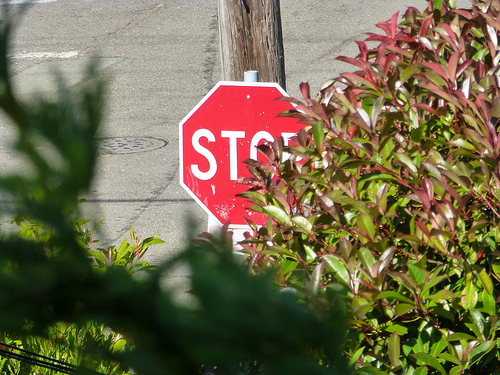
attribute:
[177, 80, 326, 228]
sign — hidden, white, red, covered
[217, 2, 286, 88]
pole — wooden, brown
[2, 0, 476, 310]
road — gray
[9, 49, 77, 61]
line — white, faded, yellow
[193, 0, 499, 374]
bush — green, attractive, blurry, red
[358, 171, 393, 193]
leaf — green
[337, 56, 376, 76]
leaf — pink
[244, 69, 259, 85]
pole — metal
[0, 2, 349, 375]
tree — green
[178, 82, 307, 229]
stop sign — red, white